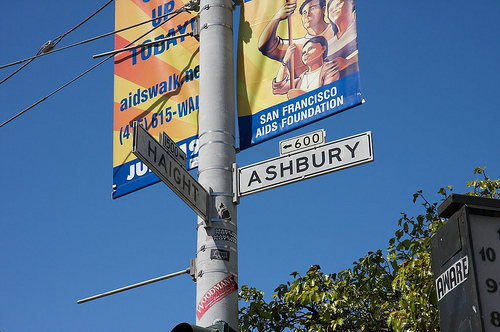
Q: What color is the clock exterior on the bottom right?
A: Black.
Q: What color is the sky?
A: Blue.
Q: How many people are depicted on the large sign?
A: Three.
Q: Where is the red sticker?
A: On the pole.